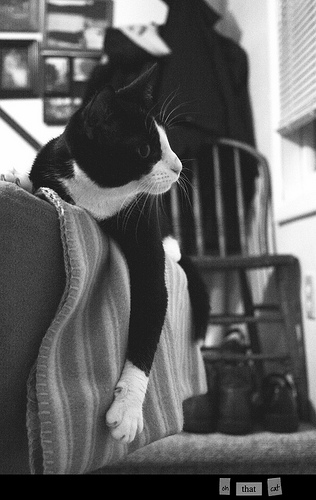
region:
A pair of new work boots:
[185, 369, 256, 436]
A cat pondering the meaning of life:
[62, 64, 223, 451]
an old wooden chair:
[162, 139, 276, 366]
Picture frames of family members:
[0, 2, 121, 132]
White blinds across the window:
[271, 6, 314, 122]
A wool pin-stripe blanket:
[53, 203, 211, 469]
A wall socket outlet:
[300, 272, 315, 310]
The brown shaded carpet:
[163, 437, 314, 474]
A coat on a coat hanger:
[167, 3, 255, 148]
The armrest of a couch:
[1, 179, 118, 485]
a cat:
[22, 58, 195, 420]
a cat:
[100, 160, 179, 338]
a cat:
[95, 191, 153, 494]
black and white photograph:
[36, 2, 260, 451]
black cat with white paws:
[102, 357, 170, 440]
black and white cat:
[64, 98, 197, 430]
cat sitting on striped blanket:
[35, 193, 215, 462]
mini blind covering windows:
[266, 0, 312, 135]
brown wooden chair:
[181, 147, 305, 385]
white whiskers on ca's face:
[111, 87, 203, 231]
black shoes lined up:
[177, 359, 308, 439]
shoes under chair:
[181, 213, 301, 431]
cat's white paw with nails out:
[104, 353, 166, 442]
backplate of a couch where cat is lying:
[0, 178, 195, 466]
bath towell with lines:
[35, 183, 210, 475]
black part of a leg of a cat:
[101, 356, 150, 444]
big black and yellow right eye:
[137, 143, 152, 160]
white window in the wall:
[280, 5, 313, 224]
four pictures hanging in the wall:
[0, 6, 110, 126]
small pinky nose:
[170, 157, 183, 172]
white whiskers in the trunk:
[125, 176, 191, 228]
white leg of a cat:
[101, 357, 147, 446]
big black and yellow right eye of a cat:
[132, 137, 158, 161]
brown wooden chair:
[143, 140, 276, 421]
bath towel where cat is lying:
[36, 181, 208, 472]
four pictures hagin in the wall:
[0, 2, 115, 124]